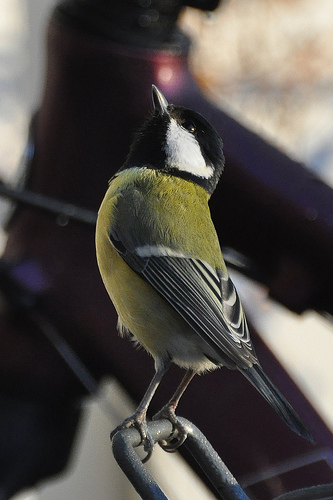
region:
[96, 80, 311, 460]
a bird on a wire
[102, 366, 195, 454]
a birds legs on a wire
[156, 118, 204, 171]
white feathers on a birds head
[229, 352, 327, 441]
tail feathers on a bird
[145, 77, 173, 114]
a beak on a bird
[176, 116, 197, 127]
a left eye on a bird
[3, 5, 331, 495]
a bird on a wire with a blurred back ground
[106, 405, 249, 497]
a blue and gray metal wire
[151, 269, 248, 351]
black and white feathers on a bird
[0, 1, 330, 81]
a red blurred red object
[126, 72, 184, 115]
mouth of the bird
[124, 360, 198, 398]
leg of the bird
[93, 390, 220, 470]
a iron stand on floor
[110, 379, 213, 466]
a iron stand on top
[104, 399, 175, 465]
a leg of the bird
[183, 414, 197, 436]
light on the iron stand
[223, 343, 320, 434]
tail of the bird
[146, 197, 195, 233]
skin of the bird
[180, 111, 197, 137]
eye of the bird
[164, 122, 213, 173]
white skin of bird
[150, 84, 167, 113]
beak of a bird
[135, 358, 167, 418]
leg of a bird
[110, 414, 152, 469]
talon of a bird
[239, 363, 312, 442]
tail of a bird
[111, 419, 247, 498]
the object is metal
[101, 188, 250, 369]
wing of a bird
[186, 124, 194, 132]
the eye is black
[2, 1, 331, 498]
the background is blurred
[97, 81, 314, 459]
a bird is perched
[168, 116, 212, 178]
cheek feathers are white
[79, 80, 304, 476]
This is a bird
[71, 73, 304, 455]
The bird is stationary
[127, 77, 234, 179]
The bird is looking up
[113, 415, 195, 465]
The bird's claws are out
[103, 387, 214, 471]
The bird is on a handle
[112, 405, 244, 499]
The handle is made of metal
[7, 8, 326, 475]
Background of the image is out of focus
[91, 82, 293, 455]
Left side of the bird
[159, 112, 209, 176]
White spot on the bird's face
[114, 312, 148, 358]
White feathers sticking out from bird's belly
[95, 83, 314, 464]
Small yellow bird with black feathers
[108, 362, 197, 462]
Pair of bird claws and legs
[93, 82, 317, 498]
Bird perched on a metal hook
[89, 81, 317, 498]
Bird standing on a metal hook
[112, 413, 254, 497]
Gray metal hook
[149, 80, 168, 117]
Small black bird beak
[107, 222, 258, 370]
White and black bird feathers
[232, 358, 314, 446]
Black and gray birdtail feathers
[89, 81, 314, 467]
Bird looking up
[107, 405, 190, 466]
Pair of bird claws